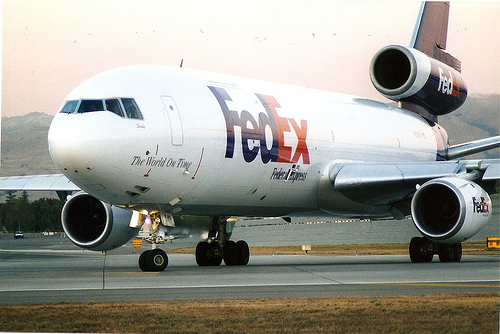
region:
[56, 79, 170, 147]
a cock pit window.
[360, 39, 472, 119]
a jet engine on the back of a plane.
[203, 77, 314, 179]
fed ex on the side of a plain.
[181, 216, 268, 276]
landing gear on a jetliner.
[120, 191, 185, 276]
front most landing gear.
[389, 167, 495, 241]
the jet engine on a left wing.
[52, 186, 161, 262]
the jet engine on a right wing.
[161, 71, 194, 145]
loading door on a jet.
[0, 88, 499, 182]
mountain range under a pink sky.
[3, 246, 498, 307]
a strip of a runway.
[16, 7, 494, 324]
A mail delivery jet is shown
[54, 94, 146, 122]
This is the cockpit wind screen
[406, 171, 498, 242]
This is one of the plane's engines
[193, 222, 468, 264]
The plane's rear landing gears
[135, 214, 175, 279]
The plane's front landing gear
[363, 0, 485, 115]
This the tail section of the plane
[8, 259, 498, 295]
This is called a taxiway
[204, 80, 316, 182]
This is the company the jet belongs to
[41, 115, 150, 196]
The jet's nose section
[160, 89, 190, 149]
This is a door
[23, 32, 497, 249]
The plane is large.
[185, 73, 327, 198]
The plane belongs to FedEx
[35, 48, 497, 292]
The plane is parked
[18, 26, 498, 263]
The plane is white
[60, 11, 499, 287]
The plane has three visible jets.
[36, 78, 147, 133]
The windows are small.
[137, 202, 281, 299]
The wheels are down.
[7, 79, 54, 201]
The mountains are rocky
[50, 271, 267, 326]
The grass is dead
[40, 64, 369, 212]
The lettering is orange and brown.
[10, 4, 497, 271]
a fedex plane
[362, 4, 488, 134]
the tail of a FedEx plane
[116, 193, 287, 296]
the wheels on a plane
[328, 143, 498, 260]
a FedEx plane engine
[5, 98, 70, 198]
a mountain in the background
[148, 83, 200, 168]
a door on a FedEx plane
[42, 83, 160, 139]
the front window on a FedEx plane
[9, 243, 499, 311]
the runway at an airport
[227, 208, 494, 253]
a building in the background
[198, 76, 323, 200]
the FedEx logo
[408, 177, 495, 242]
FedEx airplane left engine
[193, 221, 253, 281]
landing gear in contact with runway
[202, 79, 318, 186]
large painted FedEx logo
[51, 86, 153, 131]
airplane windshield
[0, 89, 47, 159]
mountains in the distance against a pink sky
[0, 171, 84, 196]
partial view of an airplane wing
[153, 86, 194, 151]
entrance door to an airplane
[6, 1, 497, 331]
FedEx plane on the runway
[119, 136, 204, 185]
Federal Express logo painted on white metal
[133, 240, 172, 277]
front wheels on an airplane